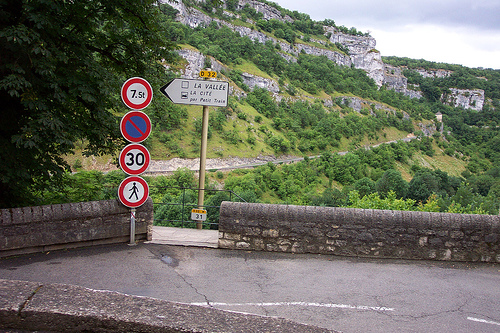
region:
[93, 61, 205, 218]
the sign is red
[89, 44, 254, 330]
the sign is red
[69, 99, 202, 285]
the sign is red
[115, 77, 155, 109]
"7.5t" on the sign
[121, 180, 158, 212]
A man walking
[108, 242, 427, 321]
This is the street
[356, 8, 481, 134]
The sky is cloudy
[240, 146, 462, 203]
Bushes alongside the road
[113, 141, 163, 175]
"30" on the sign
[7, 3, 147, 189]
Tree beside the brick fence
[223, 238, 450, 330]
White stripes on the road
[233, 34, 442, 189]
Rocks on the road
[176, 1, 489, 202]
This is a mountain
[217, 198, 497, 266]
a brick wall at the curb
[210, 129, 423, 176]
a winding road through the valley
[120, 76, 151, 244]
multiple signs on a pole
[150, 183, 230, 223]
a metal safety hand rail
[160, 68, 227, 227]
a street sign on a pole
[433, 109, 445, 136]
a building in the distance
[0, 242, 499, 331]
a designated walkway on the side of the road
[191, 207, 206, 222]
a sign on the pole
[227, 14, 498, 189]
rocky cliffs above the winding road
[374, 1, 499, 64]
cloudy skies in the distance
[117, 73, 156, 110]
red and white sign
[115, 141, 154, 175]
red and white sign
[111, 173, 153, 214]
red and white sign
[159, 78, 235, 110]
white and black sign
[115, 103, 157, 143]
red and blue sign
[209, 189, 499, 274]
low wall made of stones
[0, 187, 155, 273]
low wall made of stones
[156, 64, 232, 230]
white and black sign on pole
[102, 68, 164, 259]
four signs on a pole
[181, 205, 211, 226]
small sign on a pole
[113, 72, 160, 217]
the signs are round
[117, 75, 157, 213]
the signs are together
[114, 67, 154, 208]
four round street signs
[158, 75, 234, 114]
the sign is white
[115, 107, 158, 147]
the sign is a no sign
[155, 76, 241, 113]
the sign is an arrow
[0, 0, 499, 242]
the hillside is green and lush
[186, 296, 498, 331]
the line is painted on the concrete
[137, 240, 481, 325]
the concrete has cracks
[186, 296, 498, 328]
the line is white